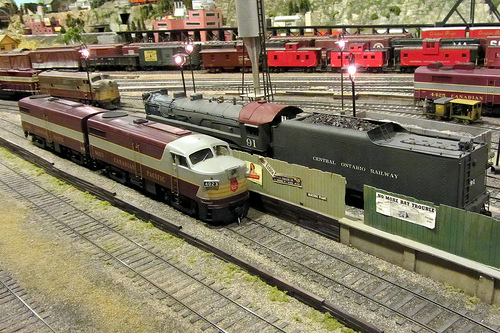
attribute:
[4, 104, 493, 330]
train — red, gray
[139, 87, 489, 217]
train — gray, red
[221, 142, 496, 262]
fence — green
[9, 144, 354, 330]
grass — green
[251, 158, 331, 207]
signs — black, white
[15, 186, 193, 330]
dead — brown